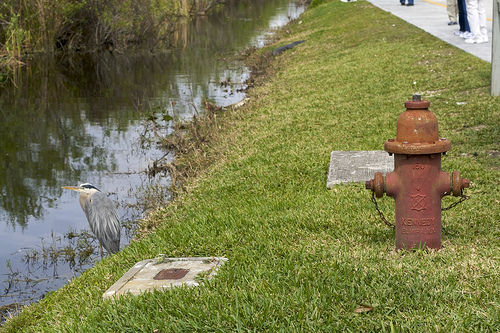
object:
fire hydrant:
[364, 91, 472, 257]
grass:
[4, 2, 499, 333]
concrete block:
[102, 256, 227, 306]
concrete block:
[323, 147, 400, 193]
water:
[0, 1, 306, 332]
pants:
[466, 0, 492, 37]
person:
[465, 1, 494, 46]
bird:
[59, 182, 123, 255]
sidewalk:
[370, 0, 494, 63]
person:
[454, 1, 472, 39]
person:
[444, 0, 462, 26]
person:
[399, 0, 420, 7]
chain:
[368, 192, 394, 234]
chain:
[442, 195, 470, 213]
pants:
[455, 0, 476, 35]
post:
[489, 0, 500, 99]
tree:
[101, 1, 212, 53]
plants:
[4, 1, 30, 66]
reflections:
[5, 1, 295, 236]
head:
[62, 181, 103, 198]